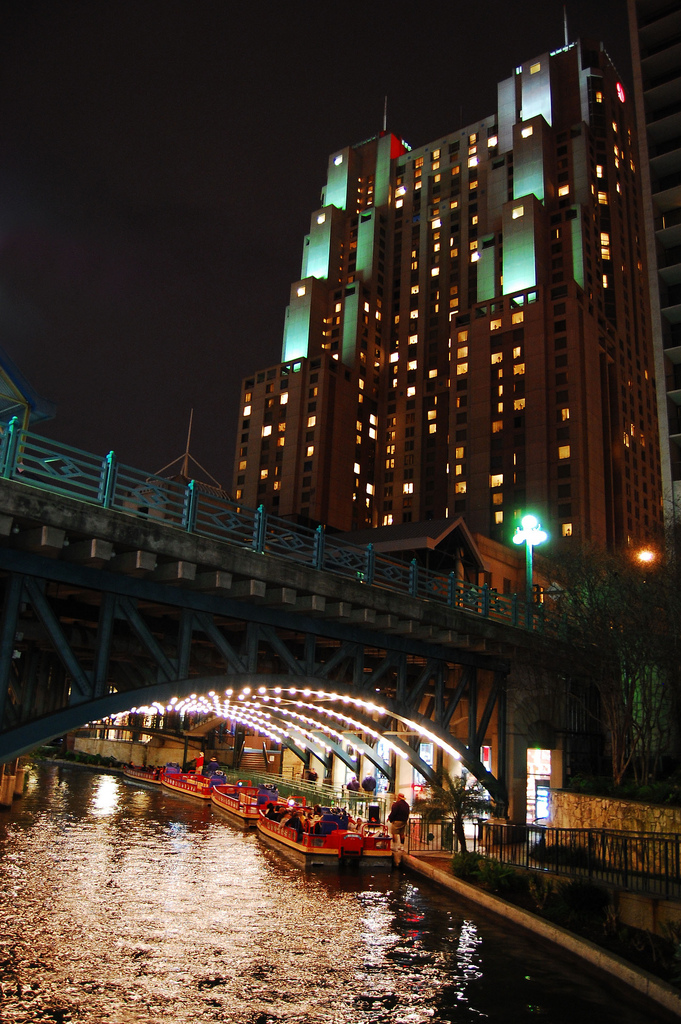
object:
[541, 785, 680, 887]
wall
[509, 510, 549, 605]
light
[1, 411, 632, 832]
bridge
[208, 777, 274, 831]
boat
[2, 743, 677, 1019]
river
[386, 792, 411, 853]
man standing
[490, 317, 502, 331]
window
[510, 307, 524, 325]
window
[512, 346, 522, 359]
window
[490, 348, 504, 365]
window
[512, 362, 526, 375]
window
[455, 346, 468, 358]
window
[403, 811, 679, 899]
gate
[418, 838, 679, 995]
sidewalk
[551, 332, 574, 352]
window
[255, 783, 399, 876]
boat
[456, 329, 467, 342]
window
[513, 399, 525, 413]
window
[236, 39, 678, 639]
building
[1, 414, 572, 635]
gate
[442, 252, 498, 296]
window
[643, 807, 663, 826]
rock